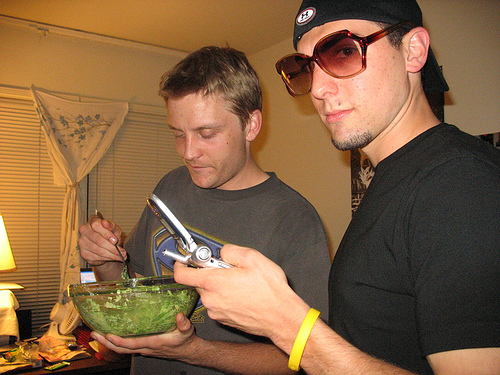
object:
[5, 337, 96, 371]
clutter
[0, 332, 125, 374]
room table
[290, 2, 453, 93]
cap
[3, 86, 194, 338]
blinds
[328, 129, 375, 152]
hair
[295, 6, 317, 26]
logo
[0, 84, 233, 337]
windows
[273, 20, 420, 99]
sunglasses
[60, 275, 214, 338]
bowl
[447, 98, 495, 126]
ground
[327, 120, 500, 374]
black shirt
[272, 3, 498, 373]
man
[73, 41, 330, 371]
man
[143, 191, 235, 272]
phone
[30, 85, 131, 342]
curtain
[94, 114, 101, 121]
flowers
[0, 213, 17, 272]
lampshade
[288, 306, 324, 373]
yellow bracelet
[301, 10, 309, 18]
print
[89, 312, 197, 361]
hand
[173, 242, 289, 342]
hand